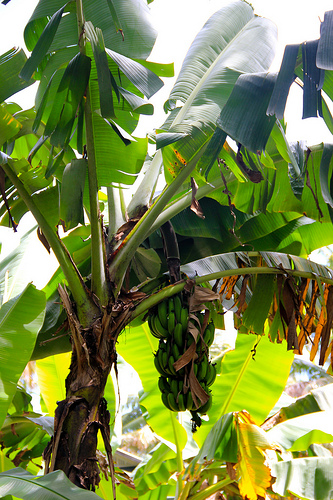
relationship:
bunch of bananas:
[153, 319, 211, 382] [142, 254, 259, 417]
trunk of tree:
[54, 425, 113, 477] [65, 125, 128, 432]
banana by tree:
[139, 267, 240, 388] [65, 125, 128, 432]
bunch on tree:
[153, 319, 211, 382] [65, 125, 128, 432]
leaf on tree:
[60, 74, 141, 179] [65, 125, 128, 432]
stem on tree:
[68, 17, 113, 101] [65, 125, 128, 432]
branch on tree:
[113, 172, 200, 257] [65, 125, 128, 432]